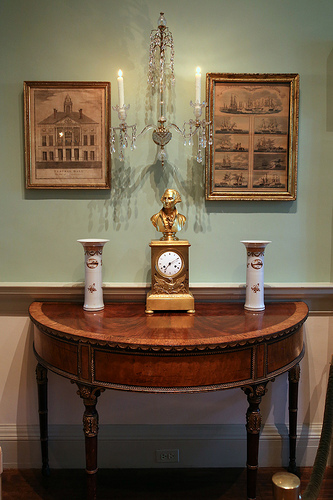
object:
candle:
[117, 68, 124, 105]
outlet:
[154, 449, 179, 465]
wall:
[0, 0, 333, 469]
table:
[29, 299, 309, 499]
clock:
[145, 239, 196, 314]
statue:
[150, 188, 187, 240]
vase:
[240, 239, 272, 311]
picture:
[205, 71, 300, 202]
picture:
[23, 80, 111, 191]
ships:
[237, 102, 270, 114]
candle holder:
[109, 104, 137, 162]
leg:
[35, 362, 50, 500]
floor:
[0, 468, 333, 500]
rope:
[303, 357, 333, 500]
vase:
[76, 238, 109, 311]